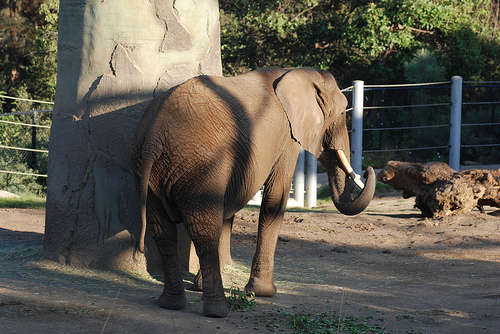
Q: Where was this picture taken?
A: Zoo.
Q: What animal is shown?
A: Elephant.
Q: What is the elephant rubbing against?
A: Stone column.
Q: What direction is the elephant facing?
A: Right.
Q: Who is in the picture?
A: No one.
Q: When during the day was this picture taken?
A: Daytime.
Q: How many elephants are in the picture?
A: One.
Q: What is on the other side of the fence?
A: Shrubbery.